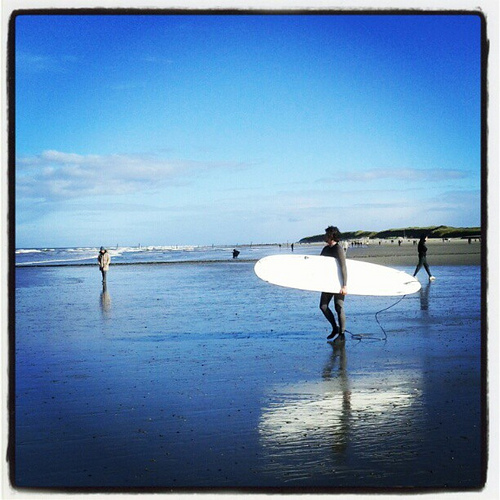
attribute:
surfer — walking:
[317, 226, 356, 342]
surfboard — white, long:
[249, 251, 429, 309]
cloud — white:
[14, 147, 165, 199]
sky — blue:
[219, 14, 476, 102]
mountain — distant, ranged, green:
[385, 228, 465, 237]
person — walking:
[414, 233, 439, 278]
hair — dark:
[326, 226, 342, 238]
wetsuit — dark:
[323, 244, 347, 322]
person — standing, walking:
[93, 247, 112, 273]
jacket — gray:
[94, 255, 109, 269]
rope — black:
[371, 302, 405, 333]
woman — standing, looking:
[87, 245, 118, 275]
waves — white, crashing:
[28, 253, 89, 277]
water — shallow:
[231, 352, 298, 382]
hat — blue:
[102, 247, 105, 253]